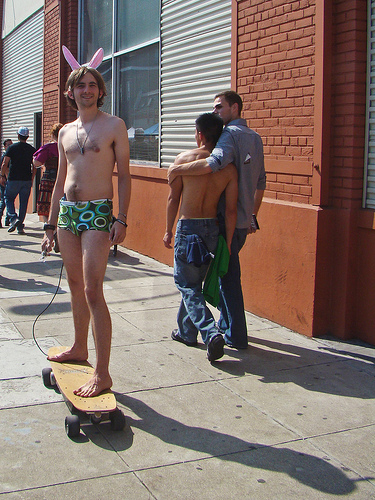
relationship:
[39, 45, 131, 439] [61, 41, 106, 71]
man with bunny ears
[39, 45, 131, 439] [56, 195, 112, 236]
man wearing swimsuit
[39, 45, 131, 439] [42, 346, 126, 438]
man riding skateboard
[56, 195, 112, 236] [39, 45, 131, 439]
swimsuit on man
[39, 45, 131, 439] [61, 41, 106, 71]
man has bunny ears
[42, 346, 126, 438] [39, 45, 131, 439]
skateboard under man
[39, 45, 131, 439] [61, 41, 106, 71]
man wearing bunny ears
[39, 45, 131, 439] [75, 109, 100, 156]
man has necklace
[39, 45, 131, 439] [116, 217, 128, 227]
man wearing wristband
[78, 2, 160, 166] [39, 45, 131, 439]
window behind man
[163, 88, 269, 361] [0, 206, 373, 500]
couple walking down sidewalk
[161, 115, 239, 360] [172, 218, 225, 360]
man wearing pants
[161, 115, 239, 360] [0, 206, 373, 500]
man walking on sidewalk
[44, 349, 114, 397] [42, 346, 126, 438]
foot on skateboard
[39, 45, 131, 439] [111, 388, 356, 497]
man casting shadow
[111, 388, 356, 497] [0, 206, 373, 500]
shadow on sidewalk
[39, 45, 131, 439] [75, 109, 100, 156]
man wearing necklace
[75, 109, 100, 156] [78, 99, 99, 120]
necklace around neck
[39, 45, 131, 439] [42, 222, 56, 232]
man wearing watch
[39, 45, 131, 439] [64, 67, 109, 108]
man has hair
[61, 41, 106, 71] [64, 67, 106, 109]
bunny ears on top of head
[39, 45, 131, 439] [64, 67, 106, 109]
man has head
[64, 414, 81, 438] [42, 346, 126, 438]
wheel on skateboard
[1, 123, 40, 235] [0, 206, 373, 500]
person on sidewalk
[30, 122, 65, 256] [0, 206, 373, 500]
person on sidewalk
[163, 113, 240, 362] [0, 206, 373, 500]
person on sidewalk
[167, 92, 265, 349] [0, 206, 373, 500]
person on sidewalk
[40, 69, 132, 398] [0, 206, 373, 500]
person on sidewalk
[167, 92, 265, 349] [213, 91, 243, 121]
person has head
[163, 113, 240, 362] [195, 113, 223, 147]
person has head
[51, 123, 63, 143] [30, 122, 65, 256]
head of a person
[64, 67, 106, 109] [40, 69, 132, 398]
head of a person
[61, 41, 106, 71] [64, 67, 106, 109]
bunny ears on head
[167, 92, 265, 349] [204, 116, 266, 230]
person has shirt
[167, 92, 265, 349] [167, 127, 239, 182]
person has left arm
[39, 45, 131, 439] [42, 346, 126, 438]
man on a skateboard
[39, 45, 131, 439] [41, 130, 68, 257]
man has right arm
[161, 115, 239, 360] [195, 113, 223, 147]
man has head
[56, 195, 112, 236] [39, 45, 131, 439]
swimsuit of man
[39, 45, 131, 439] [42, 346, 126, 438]
man on skateboard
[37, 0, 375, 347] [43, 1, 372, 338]
brick side brick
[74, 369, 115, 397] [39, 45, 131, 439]
left foot of man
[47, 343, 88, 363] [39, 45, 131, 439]
right foot of man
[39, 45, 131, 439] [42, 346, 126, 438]
man riding a skateboard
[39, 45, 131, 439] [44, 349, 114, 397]
man has foot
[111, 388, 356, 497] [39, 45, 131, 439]
shadow casted by man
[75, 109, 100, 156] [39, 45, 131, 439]
necklace of man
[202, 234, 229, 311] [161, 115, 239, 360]
shirt hanging from man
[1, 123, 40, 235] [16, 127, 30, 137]
person wearing hat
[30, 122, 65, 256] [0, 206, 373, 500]
person walking on sidewalk